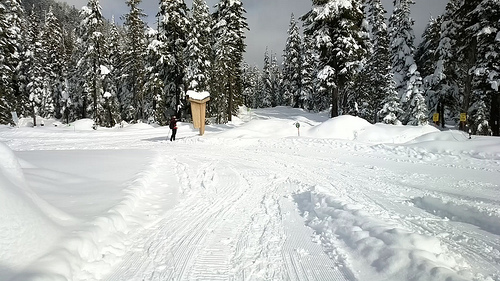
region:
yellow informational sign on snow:
[458, 110, 473, 127]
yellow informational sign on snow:
[428, 107, 443, 124]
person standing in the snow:
[161, 109, 185, 141]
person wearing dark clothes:
[161, 112, 189, 145]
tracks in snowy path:
[163, 138, 275, 279]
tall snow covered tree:
[76, 3, 127, 120]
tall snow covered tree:
[124, 5, 161, 126]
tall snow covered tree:
[306, 4, 383, 121]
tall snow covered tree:
[386, 8, 435, 131]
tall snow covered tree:
[429, 3, 475, 133]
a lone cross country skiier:
[154, 110, 199, 147]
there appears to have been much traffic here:
[144, 147, 303, 277]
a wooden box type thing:
[184, 83, 221, 135]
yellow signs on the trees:
[424, 106, 470, 132]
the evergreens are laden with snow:
[19, 10, 178, 110]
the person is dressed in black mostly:
[166, 111, 182, 141]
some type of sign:
[286, 118, 306, 137]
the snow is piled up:
[312, 111, 452, 146]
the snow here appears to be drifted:
[5, 143, 156, 258]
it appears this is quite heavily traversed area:
[200, 136, 439, 274]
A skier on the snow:
[168, 115, 177, 142]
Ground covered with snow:
[0, 106, 499, 279]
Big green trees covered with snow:
[0, 0, 498, 135]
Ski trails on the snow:
[114, 144, 496, 279]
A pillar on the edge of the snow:
[188, 89, 209, 131]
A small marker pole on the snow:
[296, 125, 303, 134]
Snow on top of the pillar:
[188, 90, 208, 96]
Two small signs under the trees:
[429, 109, 467, 122]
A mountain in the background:
[68, 1, 455, 71]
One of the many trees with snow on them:
[311, 0, 366, 116]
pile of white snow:
[189, 217, 205, 229]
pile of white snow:
[343, 208, 351, 223]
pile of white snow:
[417, 258, 434, 273]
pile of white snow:
[428, 192, 447, 205]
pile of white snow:
[411, 185, 418, 194]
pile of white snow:
[83, 243, 103, 265]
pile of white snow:
[115, 185, 130, 202]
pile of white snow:
[338, 144, 355, 160]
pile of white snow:
[301, 128, 315, 138]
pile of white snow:
[63, 172, 88, 189]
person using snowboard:
[161, 109, 188, 149]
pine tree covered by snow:
[295, 8, 417, 119]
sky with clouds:
[256, 9, 276, 47]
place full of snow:
[81, 164, 454, 239]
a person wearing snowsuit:
[168, 114, 180, 141]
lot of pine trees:
[8, 25, 240, 77]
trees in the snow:
[71, 28, 449, 233]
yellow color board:
[423, 108, 480, 141]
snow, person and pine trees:
[12, 71, 227, 238]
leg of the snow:
[168, 130, 180, 140]